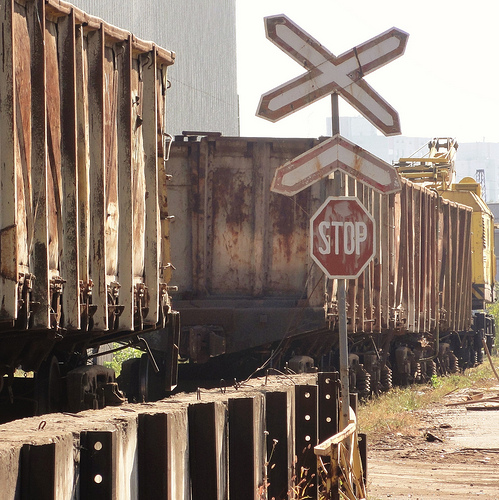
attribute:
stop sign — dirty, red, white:
[308, 196, 378, 283]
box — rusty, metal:
[173, 130, 478, 387]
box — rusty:
[3, 0, 181, 332]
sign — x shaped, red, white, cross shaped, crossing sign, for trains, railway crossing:
[254, 14, 409, 140]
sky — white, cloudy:
[236, 3, 498, 204]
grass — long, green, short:
[346, 300, 497, 441]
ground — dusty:
[360, 309, 498, 499]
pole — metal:
[329, 89, 355, 432]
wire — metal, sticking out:
[234, 259, 316, 388]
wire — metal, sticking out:
[261, 273, 335, 381]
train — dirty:
[161, 128, 497, 405]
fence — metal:
[313, 403, 366, 499]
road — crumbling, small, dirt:
[367, 356, 498, 497]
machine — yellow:
[396, 138, 498, 319]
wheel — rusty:
[438, 341, 461, 377]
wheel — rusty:
[393, 344, 418, 386]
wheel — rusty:
[364, 350, 388, 395]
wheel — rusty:
[290, 354, 318, 377]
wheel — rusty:
[33, 352, 119, 414]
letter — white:
[316, 219, 332, 258]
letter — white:
[331, 217, 346, 256]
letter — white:
[342, 217, 359, 259]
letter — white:
[354, 216, 370, 256]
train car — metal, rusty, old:
[170, 128, 475, 399]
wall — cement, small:
[3, 367, 342, 499]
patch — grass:
[355, 354, 498, 440]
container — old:
[1, 1, 178, 358]